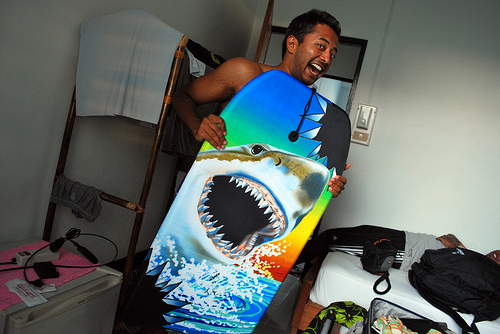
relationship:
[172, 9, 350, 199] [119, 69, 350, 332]
man holding surfboard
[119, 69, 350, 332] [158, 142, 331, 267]
surfboard has shark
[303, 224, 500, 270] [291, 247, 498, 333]
person laying on bed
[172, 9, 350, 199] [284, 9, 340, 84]
man has head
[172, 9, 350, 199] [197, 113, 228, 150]
man has hand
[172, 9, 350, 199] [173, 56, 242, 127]
man has arm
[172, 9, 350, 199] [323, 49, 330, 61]
man has nose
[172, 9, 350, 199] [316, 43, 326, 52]
man has eye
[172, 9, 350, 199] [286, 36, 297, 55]
man has ear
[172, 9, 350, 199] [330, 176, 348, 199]
man has hand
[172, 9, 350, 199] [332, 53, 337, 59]
man has eye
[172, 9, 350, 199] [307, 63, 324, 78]
man has mouth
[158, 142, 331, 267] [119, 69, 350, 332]
shark on front of surfboard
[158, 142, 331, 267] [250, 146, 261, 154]
shark has eye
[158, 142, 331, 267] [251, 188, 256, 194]
shark has tooth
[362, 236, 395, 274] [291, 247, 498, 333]
camera on top of bed